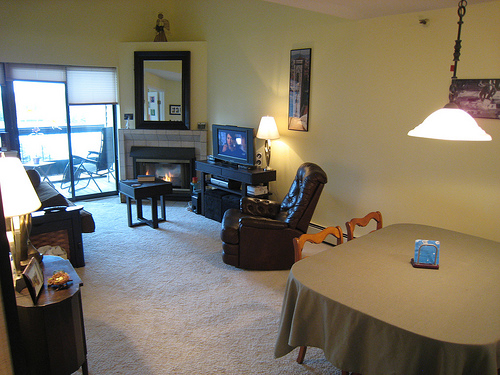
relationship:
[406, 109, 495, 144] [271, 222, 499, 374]
light above table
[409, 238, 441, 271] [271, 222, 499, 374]
napkin holder on table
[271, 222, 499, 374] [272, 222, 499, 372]
table has cloth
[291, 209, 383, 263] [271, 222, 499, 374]
chairs at table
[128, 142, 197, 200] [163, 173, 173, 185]
fireplace has flames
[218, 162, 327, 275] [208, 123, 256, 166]
recliner near television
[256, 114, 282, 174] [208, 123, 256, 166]
lamp next to television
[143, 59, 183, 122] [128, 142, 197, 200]
mirror above fireplace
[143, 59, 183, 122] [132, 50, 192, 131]
mirror has frame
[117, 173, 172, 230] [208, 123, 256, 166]
table in front of television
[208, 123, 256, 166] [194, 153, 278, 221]
television on table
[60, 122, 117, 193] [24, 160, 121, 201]
chairs on deck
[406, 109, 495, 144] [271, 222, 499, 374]
light over table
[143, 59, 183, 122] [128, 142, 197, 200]
mirror over fireplace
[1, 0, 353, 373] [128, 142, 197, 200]
living room has fireplace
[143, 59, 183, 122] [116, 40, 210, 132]
mirror on wall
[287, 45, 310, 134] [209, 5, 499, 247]
picture on wall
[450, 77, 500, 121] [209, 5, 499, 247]
picture on wall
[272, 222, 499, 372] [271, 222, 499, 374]
cloth on table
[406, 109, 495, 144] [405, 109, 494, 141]
light has shade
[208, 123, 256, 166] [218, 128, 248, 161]
television has screen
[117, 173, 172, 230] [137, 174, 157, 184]
table has book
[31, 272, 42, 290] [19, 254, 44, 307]
picture in frame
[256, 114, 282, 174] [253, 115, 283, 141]
lamp has shade